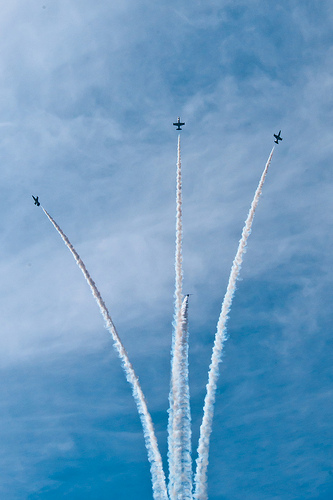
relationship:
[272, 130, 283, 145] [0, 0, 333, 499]
jet in sky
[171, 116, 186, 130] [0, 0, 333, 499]
jet in sky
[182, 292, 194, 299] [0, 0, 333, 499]
jet in sky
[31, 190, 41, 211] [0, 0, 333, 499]
jet in sky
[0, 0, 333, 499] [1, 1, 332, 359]
sky that cloudy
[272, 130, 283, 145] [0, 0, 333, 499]
aircraft flying in sky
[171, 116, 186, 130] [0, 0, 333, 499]
aircraft flying in sky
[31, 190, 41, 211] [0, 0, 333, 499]
aircraft flying in sky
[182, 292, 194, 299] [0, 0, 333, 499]
aircraft flying in sky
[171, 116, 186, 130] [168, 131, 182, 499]
jet that leaving thick contrails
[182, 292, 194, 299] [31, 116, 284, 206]
jet below or jets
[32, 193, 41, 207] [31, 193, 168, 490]
jet turning left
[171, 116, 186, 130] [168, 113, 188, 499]
center jet that flying upwards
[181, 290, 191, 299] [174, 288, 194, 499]
bottom jet flies towards camera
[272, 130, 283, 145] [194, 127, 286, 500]
rightmost jet banking right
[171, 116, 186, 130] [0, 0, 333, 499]
jet in a blue sky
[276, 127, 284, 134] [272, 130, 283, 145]
nose of blue jet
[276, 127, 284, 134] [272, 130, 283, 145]
nose of a blue jet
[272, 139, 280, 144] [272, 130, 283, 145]
tail of blue jet